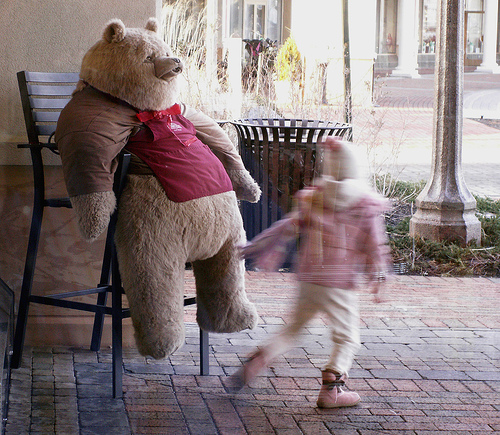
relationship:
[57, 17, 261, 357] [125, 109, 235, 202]
teddy bear wearing apron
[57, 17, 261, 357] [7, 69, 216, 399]
teddy bear sitting in chair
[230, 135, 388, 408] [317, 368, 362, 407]
girl wearing boot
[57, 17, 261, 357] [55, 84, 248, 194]
teddy bear wearing t shirt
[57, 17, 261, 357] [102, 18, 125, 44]
teddy bear has ear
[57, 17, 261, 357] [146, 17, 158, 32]
teddy bear has ear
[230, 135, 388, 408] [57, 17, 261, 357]
girl running by teddy bear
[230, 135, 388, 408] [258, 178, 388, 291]
girl wearing coat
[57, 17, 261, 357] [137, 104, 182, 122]
teddy bear wearing bowtie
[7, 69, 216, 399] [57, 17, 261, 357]
chair under teddy bear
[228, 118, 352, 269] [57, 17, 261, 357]
garbage can next to teddy bear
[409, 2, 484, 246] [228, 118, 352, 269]
lamp post beside garbage can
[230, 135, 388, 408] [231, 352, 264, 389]
girl wearing boot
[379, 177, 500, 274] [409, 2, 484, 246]
grass surrounding lamp post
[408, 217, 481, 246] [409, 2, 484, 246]
base of lamp post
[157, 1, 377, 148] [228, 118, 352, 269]
grasses behind garbage can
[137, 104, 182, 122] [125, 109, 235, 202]
bowtie on top of apron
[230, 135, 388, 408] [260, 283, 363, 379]
girl wearing pants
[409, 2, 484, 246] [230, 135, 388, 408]
lamp post to right of girl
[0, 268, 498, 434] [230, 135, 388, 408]
sidewalk under girl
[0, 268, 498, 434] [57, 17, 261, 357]
sidewalk under teddy bear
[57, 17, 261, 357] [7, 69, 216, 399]
teddy bear located in chair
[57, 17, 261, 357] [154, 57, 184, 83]
teddy bear has snout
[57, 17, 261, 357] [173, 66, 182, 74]
teddy bear has mouth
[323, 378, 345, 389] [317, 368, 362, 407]
bow tied on boot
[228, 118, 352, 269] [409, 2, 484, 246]
garbage can next to lamp post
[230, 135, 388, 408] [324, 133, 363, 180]
girl wearing hat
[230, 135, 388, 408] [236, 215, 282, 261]
girl wearing scarf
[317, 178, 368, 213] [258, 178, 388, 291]
hood attached to coat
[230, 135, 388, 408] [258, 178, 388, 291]
girl has coat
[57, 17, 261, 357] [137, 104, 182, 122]
teddy bear has bowtie